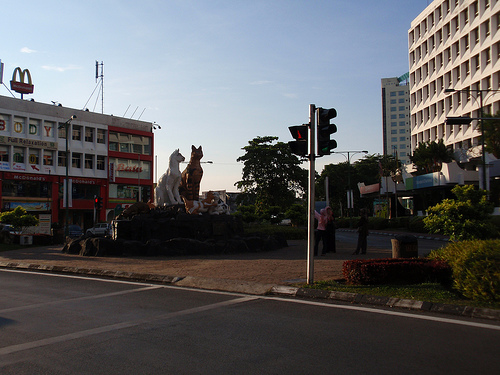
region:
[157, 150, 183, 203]
a large white cat sculpture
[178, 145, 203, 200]
a large brown cat sculpture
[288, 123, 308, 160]
a do not walk signal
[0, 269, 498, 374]
a paved city street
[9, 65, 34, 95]
a McDonald's promotional sign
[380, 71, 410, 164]
large building in distance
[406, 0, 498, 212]
large building in distance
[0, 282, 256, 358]
a marked pedestrian crossing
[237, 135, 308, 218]
large green tree in distance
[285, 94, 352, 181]
a black traffic light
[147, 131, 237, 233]
a statute of two cats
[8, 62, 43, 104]
a McDonald's sign above building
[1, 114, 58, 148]
letters on building spell Body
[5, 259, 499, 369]
white lines on the road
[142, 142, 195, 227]
a white cat statute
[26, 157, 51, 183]
a red arrow on building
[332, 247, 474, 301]
short red bushes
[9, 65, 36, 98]
mcdonalds sign above the building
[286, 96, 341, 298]
stoplight beside the road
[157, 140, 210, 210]
oversized animal figures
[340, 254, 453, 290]
dark red bush on side of road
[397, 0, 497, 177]
beige office building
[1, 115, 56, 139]
BODY spelled on side of building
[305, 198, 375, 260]
group of people observing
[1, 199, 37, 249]
green tree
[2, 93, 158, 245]
red and white building with many logos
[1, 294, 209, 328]
crosswalk for the pedestrians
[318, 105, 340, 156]
traffic light for vehicles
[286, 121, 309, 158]
light for pedestrians to walk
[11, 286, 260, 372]
street where vehicles travel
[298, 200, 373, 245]
people outside on sidewalk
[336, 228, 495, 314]
bushes on the sidewalk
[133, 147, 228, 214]
statues in a center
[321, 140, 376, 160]
lights hanging over street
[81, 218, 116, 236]
vehicle on the road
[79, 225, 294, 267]
rocks surrounding the statues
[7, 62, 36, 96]
A Mcdonalds restaurant sign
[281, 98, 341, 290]
Traffic and crosswalk light post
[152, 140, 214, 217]
Two large cat statues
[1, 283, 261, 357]
white lines for crosswalk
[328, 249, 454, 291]
short red trimmed bushes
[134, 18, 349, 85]
blue sky with no clouds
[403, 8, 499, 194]
tall building with many windows.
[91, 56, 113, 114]
sign on top of building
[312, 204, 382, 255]
group of people admiring a statue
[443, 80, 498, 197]
street lights on a post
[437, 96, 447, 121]
A window on a building.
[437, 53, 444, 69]
A window on a building.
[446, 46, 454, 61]
A window on a building.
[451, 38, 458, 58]
A window on a building.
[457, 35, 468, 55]
A window on a building.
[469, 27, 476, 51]
A window on a building.